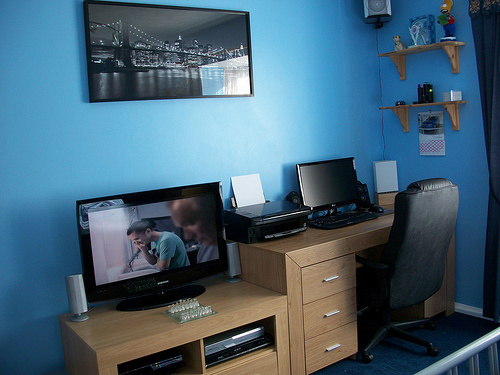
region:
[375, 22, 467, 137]
two wooden shelves on the wall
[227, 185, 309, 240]
black printer on the desk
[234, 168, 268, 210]
white paper in the black printer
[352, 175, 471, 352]
black leather swivel chair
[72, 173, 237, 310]
flat black screen TV on table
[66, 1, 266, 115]
black and whie photograph hung on the wall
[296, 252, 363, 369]
three drawers on the desk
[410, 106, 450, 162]
calendar hung on the wall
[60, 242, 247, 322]
two silver speakers on either side of the TV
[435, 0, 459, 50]
bart simpson toy on shelf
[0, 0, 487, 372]
walls of room are blue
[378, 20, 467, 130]
wall has two shelves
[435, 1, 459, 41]
shelf has a Simpson figurine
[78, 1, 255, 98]
bridge picture on the wall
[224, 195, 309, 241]
printer is on top of desk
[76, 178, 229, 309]
flat screen tv next to printer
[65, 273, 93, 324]
speaker is next to tv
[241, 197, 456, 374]
desk has three drawer on the left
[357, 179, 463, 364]
desk chair is black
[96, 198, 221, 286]
tv shows two men on screen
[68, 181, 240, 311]
small black flat screen t.v. on desk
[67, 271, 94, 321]
small silver cpu speaker sitting near flat screen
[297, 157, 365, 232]
black desk top cpu sitting on desk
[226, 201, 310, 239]
black printer with paper sitting on desk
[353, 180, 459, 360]
black cpu chair sitting near desk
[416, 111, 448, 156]
small calendar hanging on wall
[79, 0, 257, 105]
large framed picture hanging on wall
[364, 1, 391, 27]
small silver speaker hanging on wall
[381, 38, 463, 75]
wooden shelf hanging on wall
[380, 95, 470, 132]
wooden shelf hanging on wall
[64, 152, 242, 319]
a flat screen television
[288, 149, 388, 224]
a black computer monitor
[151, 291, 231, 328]
a small glass chess set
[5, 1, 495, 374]
the wall is blue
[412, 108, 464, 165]
a calendar with the dates crossed off in red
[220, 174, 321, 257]
a black printer with a scanner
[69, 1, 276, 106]
a framed black and white photo of new York City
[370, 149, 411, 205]
a white speaker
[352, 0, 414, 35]
a wall mounted speaker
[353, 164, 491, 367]
a black leather office chair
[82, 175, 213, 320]
that is a laptop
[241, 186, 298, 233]
that is a laptop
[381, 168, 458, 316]
that is a chair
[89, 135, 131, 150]
the wall is painted blue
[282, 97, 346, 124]
the wall is painted blue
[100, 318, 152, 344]
that is a wooden cabinet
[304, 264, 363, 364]
a chest of drawers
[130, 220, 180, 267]
that is a person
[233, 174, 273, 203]
that is a calender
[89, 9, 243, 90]
a painting on the waall